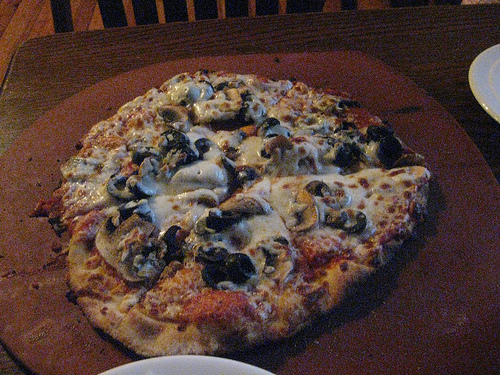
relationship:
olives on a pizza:
[203, 247, 253, 282] [60, 73, 452, 342]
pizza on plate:
[58, 67, 432, 357] [1, 48, 496, 372]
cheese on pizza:
[146, 154, 220, 226] [58, 67, 432, 357]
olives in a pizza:
[198, 245, 257, 287] [58, 67, 432, 357]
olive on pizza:
[201, 253, 251, 281] [58, 67, 432, 357]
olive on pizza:
[333, 142, 363, 166] [58, 67, 432, 357]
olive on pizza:
[107, 166, 142, 198] [58, 67, 432, 357]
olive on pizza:
[202, 245, 252, 286] [59, 40, 423, 354]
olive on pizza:
[331, 140, 360, 170] [59, 40, 423, 354]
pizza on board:
[90, 84, 418, 338] [23, 43, 480, 358]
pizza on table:
[42, 37, 470, 342] [56, 67, 433, 357]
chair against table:
[59, 2, 374, 28] [23, 28, 498, 358]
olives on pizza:
[189, 237, 259, 297] [41, 63, 447, 362]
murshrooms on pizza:
[219, 195, 262, 217] [58, 67, 432, 357]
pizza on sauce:
[41, 63, 447, 362] [297, 227, 348, 271]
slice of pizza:
[258, 164, 438, 316] [58, 67, 432, 357]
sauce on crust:
[33, 183, 64, 232] [64, 263, 147, 341]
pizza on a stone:
[58, 67, 432, 357] [332, 34, 462, 165]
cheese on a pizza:
[182, 165, 229, 181] [58, 67, 432, 357]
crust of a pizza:
[87, 287, 314, 354] [58, 67, 432, 357]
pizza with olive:
[58, 67, 432, 357] [329, 138, 373, 171]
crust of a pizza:
[64, 263, 147, 341] [60, 73, 452, 342]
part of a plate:
[470, 62, 484, 79] [463, 37, 498, 139]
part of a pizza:
[470, 62, 484, 79] [58, 67, 432, 357]